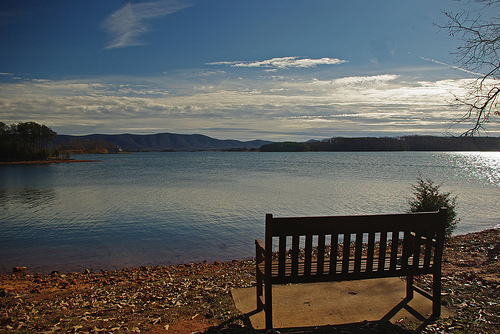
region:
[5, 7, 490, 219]
Peaceful view from the bench.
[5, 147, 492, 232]
Smooth water.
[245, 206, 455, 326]
Wooden bench on the shore.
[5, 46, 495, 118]
White clouds in the blue sky.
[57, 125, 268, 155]
Mountains in the background.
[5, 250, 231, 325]
Dead leaves falling on the ground.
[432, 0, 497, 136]
Leafless tree.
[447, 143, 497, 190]
Reflection of the sun on the water.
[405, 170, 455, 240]
The small tree is growing on the shore.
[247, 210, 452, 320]
The wooden bench is empty.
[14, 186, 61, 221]
reflection of a tree on the water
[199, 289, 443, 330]
shadow of the bench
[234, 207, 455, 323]
empty bench facing the water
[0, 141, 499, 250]
large body of water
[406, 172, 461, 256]
short green shrub next to the bench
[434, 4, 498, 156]
part of a leafless tree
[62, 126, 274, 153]
short mountains in the distance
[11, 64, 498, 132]
white clouds in the sky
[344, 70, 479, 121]
sun hidden behind the clouds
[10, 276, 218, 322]
leaves on the ground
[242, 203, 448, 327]
wooden bench overlooking water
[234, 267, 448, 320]
cement pad bench is sitting on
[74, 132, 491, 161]
hilltops in the background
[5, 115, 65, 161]
trees growing in the distance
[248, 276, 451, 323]
legs of wooden bench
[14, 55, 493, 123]
long line of clouds in the sky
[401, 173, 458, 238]
bush growing beside bench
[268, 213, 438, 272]
back of wooden bench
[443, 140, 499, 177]
sunlight reflected in water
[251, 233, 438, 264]
armrests of wooden bench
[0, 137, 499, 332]
The bench is on the bank of the water.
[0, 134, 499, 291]
The water is calm.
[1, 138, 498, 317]
The water is sedate.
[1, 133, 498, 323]
The water is serene.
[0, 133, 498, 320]
The water is tranquil.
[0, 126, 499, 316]
The water is mellow.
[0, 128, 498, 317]
The water is untroubled.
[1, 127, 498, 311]
The water is pacifying.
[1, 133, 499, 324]
The water is amenable.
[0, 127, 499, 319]
The water is mild.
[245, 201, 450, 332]
wooden bench on cement pad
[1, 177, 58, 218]
trees reflected in water's surface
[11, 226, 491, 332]
shoreline along water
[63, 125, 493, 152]
range of mountains on the horizon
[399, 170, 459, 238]
plant growing by water's edge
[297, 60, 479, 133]
cloud backlit by the sun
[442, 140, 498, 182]
sunlight shining down on water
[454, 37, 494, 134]
branches hanging over water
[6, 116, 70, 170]
trees in front of mountains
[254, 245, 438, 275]
wooden slat seat of bench